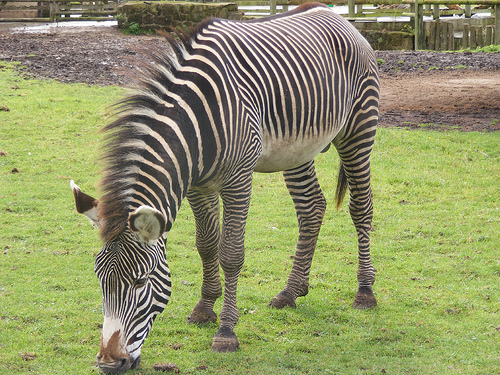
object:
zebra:
[69, 3, 384, 373]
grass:
[3, 118, 65, 371]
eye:
[134, 277, 148, 288]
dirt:
[73, 40, 124, 77]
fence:
[416, 12, 500, 53]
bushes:
[117, 4, 178, 31]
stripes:
[174, 122, 189, 190]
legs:
[332, 84, 380, 308]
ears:
[127, 206, 165, 243]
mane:
[94, 19, 205, 251]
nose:
[95, 348, 134, 373]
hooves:
[359, 295, 377, 311]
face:
[94, 236, 155, 371]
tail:
[333, 151, 350, 210]